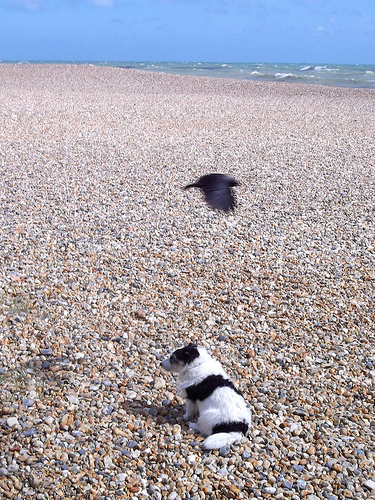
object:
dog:
[159, 343, 251, 451]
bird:
[181, 172, 241, 214]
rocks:
[365, 477, 375, 490]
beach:
[0, 60, 375, 498]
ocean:
[164, 59, 373, 89]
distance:
[1, 59, 373, 88]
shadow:
[3, 354, 62, 391]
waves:
[331, 77, 373, 84]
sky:
[0, 0, 374, 67]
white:
[279, 72, 287, 79]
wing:
[206, 185, 235, 212]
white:
[210, 395, 237, 416]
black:
[182, 350, 195, 359]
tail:
[200, 432, 243, 450]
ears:
[183, 350, 189, 358]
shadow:
[120, 398, 183, 425]